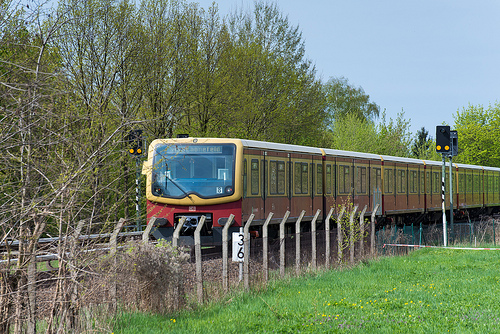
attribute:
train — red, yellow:
[146, 134, 499, 249]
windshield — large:
[153, 140, 228, 197]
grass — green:
[168, 248, 499, 333]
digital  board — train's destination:
[164, 141, 225, 157]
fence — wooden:
[7, 196, 497, 334]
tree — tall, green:
[211, 12, 322, 144]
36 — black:
[235, 232, 246, 261]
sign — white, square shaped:
[233, 231, 248, 265]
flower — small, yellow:
[327, 299, 331, 309]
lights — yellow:
[437, 145, 451, 153]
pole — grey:
[439, 160, 450, 249]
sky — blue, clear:
[3, 3, 498, 139]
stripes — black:
[442, 182, 450, 205]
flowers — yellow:
[169, 272, 485, 331]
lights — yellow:
[127, 147, 141, 157]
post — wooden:
[192, 215, 206, 303]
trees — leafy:
[2, 4, 500, 220]